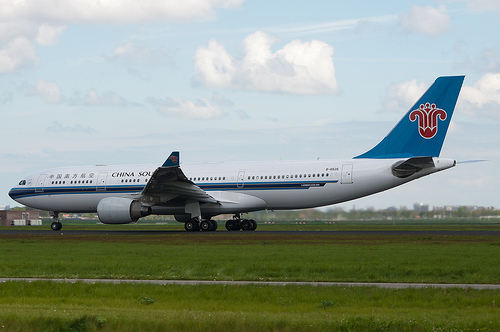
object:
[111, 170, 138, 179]
china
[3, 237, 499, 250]
grassy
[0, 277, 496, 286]
sidewalk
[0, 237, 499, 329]
grass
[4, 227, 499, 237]
runway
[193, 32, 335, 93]
cloud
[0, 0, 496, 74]
sky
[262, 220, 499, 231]
grassy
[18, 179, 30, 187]
windshield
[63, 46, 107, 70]
blue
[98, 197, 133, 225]
engine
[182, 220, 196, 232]
wheels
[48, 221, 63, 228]
wheel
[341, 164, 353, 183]
door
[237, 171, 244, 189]
door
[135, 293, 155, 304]
green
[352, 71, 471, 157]
tail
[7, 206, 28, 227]
buildings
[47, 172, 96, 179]
writing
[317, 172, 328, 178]
windows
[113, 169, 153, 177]
title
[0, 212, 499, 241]
tarmac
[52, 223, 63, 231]
gear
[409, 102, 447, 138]
design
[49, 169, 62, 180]
chinese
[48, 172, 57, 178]
characters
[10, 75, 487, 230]
airplane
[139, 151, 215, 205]
wing